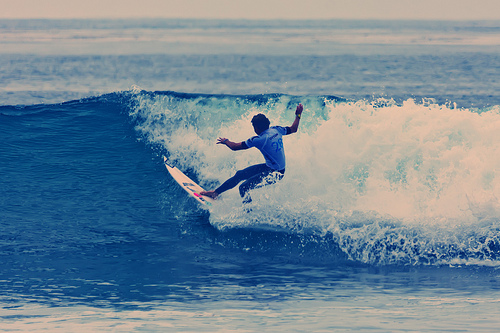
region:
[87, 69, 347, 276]
man surfing on wave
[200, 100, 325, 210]
blue rashguard on man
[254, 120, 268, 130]
curly black hair on head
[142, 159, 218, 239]
surfboard on a wave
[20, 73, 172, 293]
unbroken section of wave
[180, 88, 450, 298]
broken section of wave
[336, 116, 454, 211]
white water on wave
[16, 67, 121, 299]
blue water on wave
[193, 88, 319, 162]
arms out at sides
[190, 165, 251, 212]
right foot forward on wave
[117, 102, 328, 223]
a person on a surfboard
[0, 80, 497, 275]
a man surfing in the ocean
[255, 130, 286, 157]
number 28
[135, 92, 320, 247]
a man on a white surfboard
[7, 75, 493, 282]
a man riding a wave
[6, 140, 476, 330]
a surfboard in the water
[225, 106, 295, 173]
number 28 on a shirt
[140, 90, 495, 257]
a white wave cap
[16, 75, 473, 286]
a man on a white surfboard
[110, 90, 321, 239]
man with a number 28 jersey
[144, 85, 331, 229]
person in the water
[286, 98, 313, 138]
arm of the person in the air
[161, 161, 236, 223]
board under the man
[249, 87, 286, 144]
head of the man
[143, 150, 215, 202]
white under the board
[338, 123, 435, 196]
white water in the ocean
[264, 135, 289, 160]
number on the wetsuit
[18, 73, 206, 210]
wave in the water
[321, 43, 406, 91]
still water behind wave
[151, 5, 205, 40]
sky above the water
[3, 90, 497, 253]
big tide in ocean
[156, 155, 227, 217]
surfboard in water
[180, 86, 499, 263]
white water on top of wave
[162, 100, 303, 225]
man surfing in ocean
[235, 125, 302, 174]
short sleeve blue shirt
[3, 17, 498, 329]
large body of rough water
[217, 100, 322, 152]
arms out to the sides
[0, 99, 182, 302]
dark blue water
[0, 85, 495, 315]
surfboard in the midst of a wave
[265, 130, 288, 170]
numbers on blue t shirt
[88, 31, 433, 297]
the man is surfing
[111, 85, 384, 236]
the man is surfing